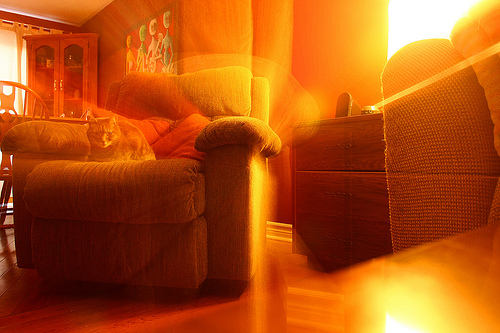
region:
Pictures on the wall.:
[119, 9, 181, 78]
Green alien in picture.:
[132, 27, 151, 67]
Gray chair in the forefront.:
[9, 48, 281, 290]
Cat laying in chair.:
[82, 110, 163, 166]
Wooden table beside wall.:
[283, 116, 390, 270]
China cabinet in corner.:
[19, 30, 99, 121]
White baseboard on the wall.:
[266, 213, 293, 245]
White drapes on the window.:
[2, 18, 29, 107]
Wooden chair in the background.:
[0, 73, 52, 270]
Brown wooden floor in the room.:
[0, 206, 392, 329]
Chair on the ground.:
[13, 49, 319, 329]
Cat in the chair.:
[73, 77, 226, 202]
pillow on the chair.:
[143, 68, 221, 167]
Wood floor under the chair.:
[60, 277, 157, 329]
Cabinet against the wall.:
[5, 14, 116, 139]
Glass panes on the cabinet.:
[30, 33, 105, 119]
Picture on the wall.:
[105, 14, 212, 95]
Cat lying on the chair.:
[47, 60, 234, 182]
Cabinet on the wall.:
[286, 64, 431, 291]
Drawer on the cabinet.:
[301, 117, 377, 158]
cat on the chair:
[63, 98, 172, 211]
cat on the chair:
[73, 88, 150, 166]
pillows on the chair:
[136, 98, 211, 180]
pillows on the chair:
[109, 100, 234, 198]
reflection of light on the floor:
[349, 262, 493, 330]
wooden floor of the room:
[2, 217, 498, 331]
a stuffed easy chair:
[2, 69, 282, 295]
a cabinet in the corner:
[24, 33, 99, 121]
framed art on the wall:
[117, 4, 182, 88]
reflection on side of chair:
[250, 160, 266, 278]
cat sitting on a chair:
[82, 114, 154, 164]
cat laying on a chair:
[82, 115, 157, 165]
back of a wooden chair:
[1, 79, 28, 124]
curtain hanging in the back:
[18, 22, 63, 113]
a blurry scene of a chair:
[6, 11, 498, 301]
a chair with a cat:
[7, 66, 272, 302]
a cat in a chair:
[71, 98, 173, 174]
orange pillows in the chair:
[135, 108, 203, 165]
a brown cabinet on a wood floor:
[283, 103, 406, 275]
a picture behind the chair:
[111, 0, 203, 95]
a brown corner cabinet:
[26, 31, 101, 123]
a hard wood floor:
[252, 263, 374, 325]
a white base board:
[257, 220, 298, 252]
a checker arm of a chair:
[367, 32, 487, 261]